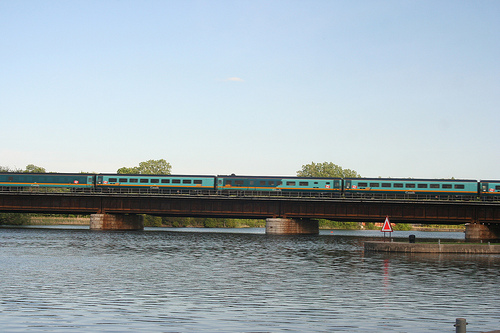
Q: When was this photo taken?
A: Daytime.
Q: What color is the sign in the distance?
A: Red.